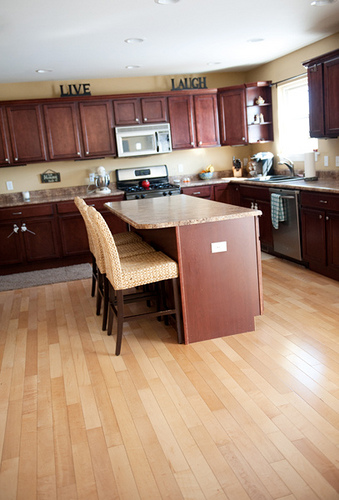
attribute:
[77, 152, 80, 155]
knob — grey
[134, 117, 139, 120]
knob — grey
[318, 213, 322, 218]
knob — grey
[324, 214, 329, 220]
knob — grey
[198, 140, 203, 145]
knob — grey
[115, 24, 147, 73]
recessed lights — white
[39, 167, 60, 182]
sign — small, wooden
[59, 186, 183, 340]
chairs — three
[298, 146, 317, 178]
towels — paper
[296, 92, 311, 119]
ground — granite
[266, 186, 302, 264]
dishwasher — stainless steel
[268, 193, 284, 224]
towel — green, white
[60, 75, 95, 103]
art — that says live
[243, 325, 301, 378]
flooring — hardwood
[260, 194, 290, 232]
cloth seat — white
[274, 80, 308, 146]
window — open, bright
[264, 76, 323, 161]
window — bright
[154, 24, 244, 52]
floor — wood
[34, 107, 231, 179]
cabinets — dark, brown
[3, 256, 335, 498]
surface — tan 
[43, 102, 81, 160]
door — cabinet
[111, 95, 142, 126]
door — cabinet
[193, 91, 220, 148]
door — cabinet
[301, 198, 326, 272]
door — cabinet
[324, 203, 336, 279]
door — cabinet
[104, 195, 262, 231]
surface — tan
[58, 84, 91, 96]
piece — wooden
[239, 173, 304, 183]
sink — stainless steel, kitchen